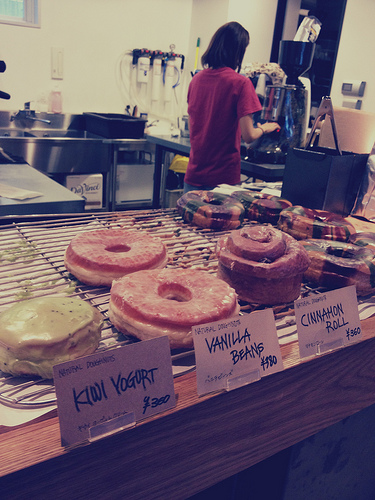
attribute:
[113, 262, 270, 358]
doughnut — big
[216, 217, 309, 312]
cinnamon roll — brown, huge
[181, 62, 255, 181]
tshirt — maroon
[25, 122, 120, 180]
sink — silver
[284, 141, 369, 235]
container — black